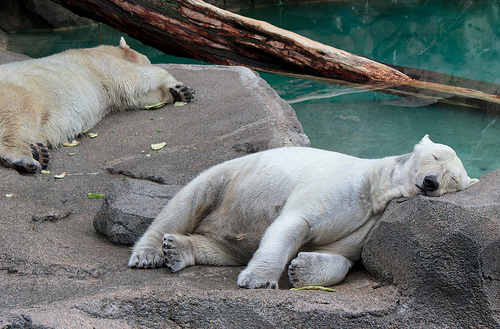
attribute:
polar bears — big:
[2, 35, 194, 175]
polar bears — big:
[127, 130, 480, 289]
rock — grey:
[99, 174, 188, 241]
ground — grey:
[0, 65, 496, 325]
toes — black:
[19, 135, 54, 183]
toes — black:
[125, 236, 167, 271]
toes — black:
[156, 230, 188, 277]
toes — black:
[234, 257, 286, 294]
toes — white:
[274, 246, 312, 296]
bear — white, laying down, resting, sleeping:
[127, 132, 478, 288]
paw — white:
[282, 245, 369, 288]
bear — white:
[154, 137, 459, 302]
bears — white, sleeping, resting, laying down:
[128, 132, 480, 292]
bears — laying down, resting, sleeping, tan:
[2, 34, 196, 173]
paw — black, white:
[156, 227, 193, 282]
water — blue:
[240, 0, 498, 157]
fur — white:
[237, 167, 312, 239]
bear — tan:
[5, 43, 192, 168]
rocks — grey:
[2, 64, 494, 326]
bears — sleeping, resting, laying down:
[0, 38, 470, 287]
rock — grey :
[359, 164, 497, 319]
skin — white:
[346, 151, 411, 226]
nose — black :
[423, 175, 445, 192]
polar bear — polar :
[124, 133, 472, 287]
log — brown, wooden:
[306, 36, 494, 131]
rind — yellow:
[145, 141, 187, 160]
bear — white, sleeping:
[123, 135, 475, 303]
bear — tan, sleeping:
[1, 33, 203, 195]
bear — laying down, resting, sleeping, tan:
[2, 30, 193, 175]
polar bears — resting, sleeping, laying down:
[2, 42, 484, 284]